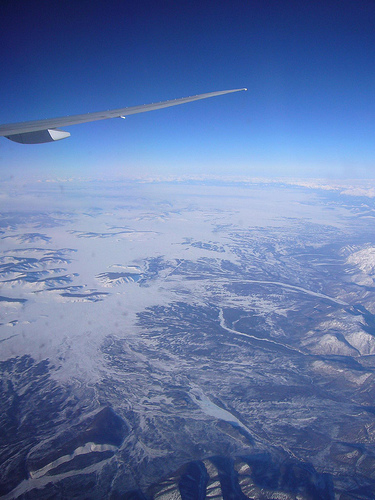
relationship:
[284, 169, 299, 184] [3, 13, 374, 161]
bag in sky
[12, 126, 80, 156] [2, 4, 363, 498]
bag in sky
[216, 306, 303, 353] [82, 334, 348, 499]
frozen river running from mountain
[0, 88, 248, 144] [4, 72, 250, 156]
airplane of an airplane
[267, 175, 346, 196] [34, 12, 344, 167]
clouds in sky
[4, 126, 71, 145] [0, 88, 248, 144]
vent under airplane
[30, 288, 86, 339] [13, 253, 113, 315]
snow covering mountains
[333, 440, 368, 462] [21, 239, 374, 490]
shadow of a mountain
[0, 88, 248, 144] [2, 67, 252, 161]
airplane of an airplane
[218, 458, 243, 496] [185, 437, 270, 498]
valley between mountain ravines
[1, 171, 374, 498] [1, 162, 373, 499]
range of snow